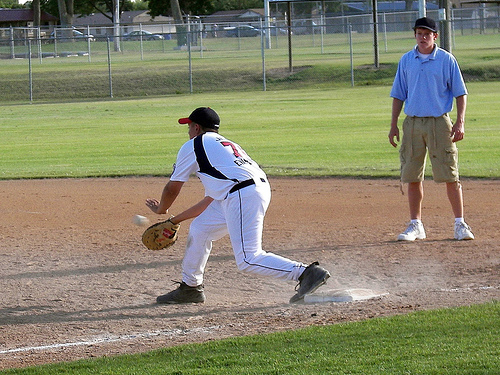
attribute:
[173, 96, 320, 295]
player — catching, playing, white, standing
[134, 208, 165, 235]
ball — thrown, white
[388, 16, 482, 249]
coach — coaching, standing, watching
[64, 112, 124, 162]
field — green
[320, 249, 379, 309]
mound — dusty, white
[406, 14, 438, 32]
hat — red